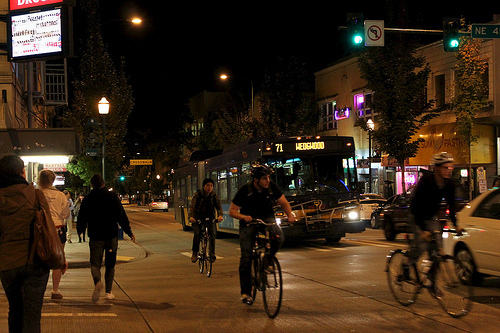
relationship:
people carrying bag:
[0, 153, 63, 333] [33, 188, 66, 270]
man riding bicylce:
[228, 163, 296, 304] [232, 203, 478, 318]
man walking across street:
[228, 163, 296, 304] [2, 259, 482, 318]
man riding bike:
[228, 163, 296, 304] [208, 219, 288, 321]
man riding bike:
[184, 175, 225, 279] [185, 212, 222, 279]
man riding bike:
[397, 152, 467, 299] [386, 227, 475, 318]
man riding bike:
[228, 163, 296, 304] [238, 214, 283, 319]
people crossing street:
[74, 175, 132, 302] [33, 189, 499, 329]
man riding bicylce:
[218, 152, 311, 331] [241, 217, 293, 319]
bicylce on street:
[241, 217, 293, 319] [156, 271, 379, 331]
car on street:
[408, 152, 498, 307] [321, 244, 496, 332]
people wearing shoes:
[76, 174, 136, 302] [83, 281, 118, 300]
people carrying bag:
[0, 153, 63, 333] [28, 185, 64, 270]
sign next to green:
[353, 8, 398, 59] [450, 38, 460, 48]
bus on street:
[189, 137, 386, 247] [137, 222, 483, 320]